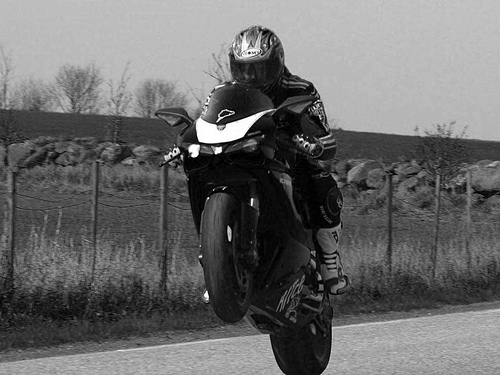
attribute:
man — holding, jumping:
[217, 27, 345, 291]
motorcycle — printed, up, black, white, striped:
[153, 81, 337, 375]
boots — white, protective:
[309, 221, 346, 293]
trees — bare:
[0, 48, 471, 168]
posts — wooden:
[2, 163, 485, 293]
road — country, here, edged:
[1, 299, 499, 374]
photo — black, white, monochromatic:
[2, 2, 498, 371]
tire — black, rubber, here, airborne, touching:
[198, 194, 258, 326]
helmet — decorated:
[232, 25, 285, 80]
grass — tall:
[2, 214, 498, 304]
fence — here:
[7, 159, 500, 279]